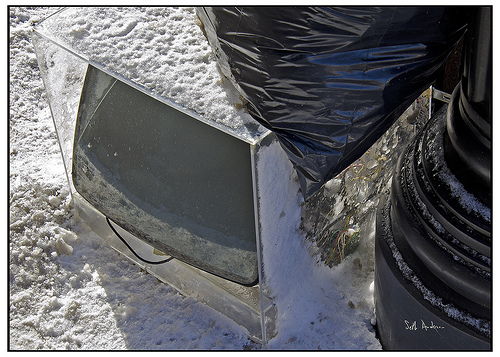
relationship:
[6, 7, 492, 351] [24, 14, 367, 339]
snow on tv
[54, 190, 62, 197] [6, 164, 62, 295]
rock in snow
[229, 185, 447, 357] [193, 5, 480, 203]
corner of filled bag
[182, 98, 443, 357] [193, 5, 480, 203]
triangular edges of wrinkled bag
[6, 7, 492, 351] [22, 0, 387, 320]
snow on case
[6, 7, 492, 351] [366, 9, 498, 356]
snow on pole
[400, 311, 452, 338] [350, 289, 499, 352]
name on bottom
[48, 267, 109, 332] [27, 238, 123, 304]
light on ground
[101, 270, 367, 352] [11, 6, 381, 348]
shadow on ground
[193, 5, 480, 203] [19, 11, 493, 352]
bag in photo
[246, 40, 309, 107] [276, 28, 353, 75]
light on bag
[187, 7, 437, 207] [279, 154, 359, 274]
bag has tip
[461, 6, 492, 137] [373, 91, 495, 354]
lamp post has base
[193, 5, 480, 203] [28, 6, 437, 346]
bag on television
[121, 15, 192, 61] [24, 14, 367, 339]
snow on tv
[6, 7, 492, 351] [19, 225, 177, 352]
snow on ground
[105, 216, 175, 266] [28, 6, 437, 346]
wire near television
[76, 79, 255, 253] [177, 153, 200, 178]
mirror seen part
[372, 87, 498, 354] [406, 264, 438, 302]
tank seen part